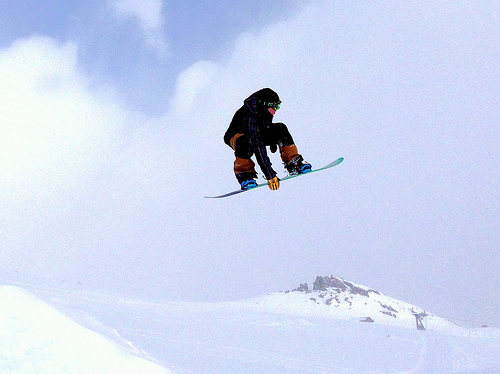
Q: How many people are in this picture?
A: One.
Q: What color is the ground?
A: White.